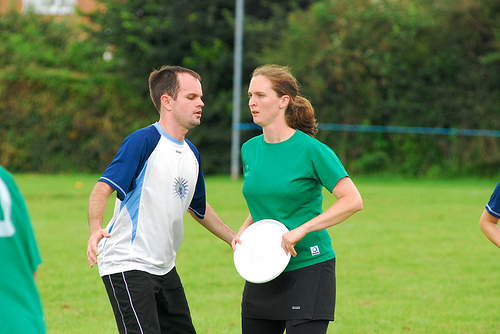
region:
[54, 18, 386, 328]
two people playing frisbee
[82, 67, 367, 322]
a couple with a white frisbee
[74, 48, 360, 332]
they look confused together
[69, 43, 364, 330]
they are trying to figure out what is going on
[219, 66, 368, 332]
this lady is holding a white frisbee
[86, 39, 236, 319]
the man has his arms extended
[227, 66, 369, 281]
she is wearing a green t-shirt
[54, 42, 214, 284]
he is wearing a blue and white shirt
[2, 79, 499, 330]
two people in this picture cannot be fully seen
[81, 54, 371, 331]
the couple is learning how to play frisbee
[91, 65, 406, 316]
people playing frisbee in park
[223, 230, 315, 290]
white frisbee in woman's hands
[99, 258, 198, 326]
bottom attire on man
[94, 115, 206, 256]
shirt on a man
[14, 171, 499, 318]
field in a park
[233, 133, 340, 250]
shirt on a woman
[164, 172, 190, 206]
image on the shirt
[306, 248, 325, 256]
tag on the shirt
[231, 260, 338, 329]
bottom attire on woman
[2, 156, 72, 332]
shirt on a person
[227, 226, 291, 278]
A white frisbee being held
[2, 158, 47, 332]
The corner of a green jersey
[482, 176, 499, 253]
An elbow with a blue sleeve in the corner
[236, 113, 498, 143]
A blue pole in the back ground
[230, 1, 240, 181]
A silver pole in the background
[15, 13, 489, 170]
The trees in the back ground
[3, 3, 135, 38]
The corner of a building can be seen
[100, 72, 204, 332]
A man in a blue shirt blocking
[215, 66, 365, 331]
A women in a green shirt with a frisbee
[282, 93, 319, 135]
The pony tail of the girl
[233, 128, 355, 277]
the shirt is green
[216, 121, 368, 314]
the shirt is green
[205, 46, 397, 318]
woman holding the frisbee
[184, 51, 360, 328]
woman holding the frisbee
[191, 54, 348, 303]
woman holding the frisbee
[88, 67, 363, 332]
two people playing frisbee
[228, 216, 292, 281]
a woman holding a white frisbee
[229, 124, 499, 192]
a net attached to a metal pole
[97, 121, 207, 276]
man wearing a white and blue shirt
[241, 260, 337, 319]
woman wearing a black skirt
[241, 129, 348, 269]
woman wearing a green shirt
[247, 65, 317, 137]
woman with red hair in a pony tail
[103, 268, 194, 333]
man wearing black pants with two white lines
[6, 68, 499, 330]
people standing in a park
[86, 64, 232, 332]
man trying to grab a frisbee